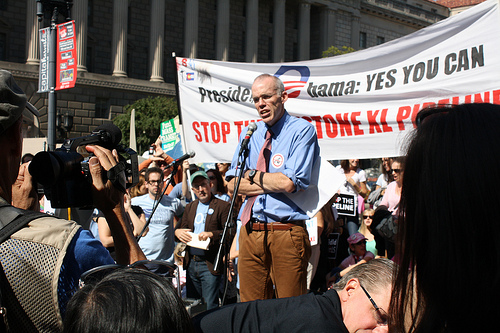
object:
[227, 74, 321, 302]
man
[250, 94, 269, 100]
glasses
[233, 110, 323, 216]
shirt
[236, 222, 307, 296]
pants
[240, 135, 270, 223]
tie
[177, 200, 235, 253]
jacket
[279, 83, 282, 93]
hair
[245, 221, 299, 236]
belt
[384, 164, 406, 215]
person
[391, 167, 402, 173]
sunglasses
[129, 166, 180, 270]
man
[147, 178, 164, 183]
glasses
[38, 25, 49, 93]
pennant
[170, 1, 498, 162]
sign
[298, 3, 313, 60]
columns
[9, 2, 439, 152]
building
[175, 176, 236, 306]
man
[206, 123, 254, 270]
microphones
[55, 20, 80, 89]
banners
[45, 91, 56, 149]
pole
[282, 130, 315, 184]
sleeves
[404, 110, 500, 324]
woman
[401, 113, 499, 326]
hair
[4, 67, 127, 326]
person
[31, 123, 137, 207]
camera